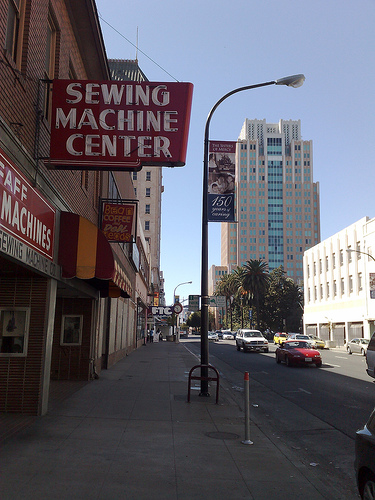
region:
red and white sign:
[51, 75, 181, 180]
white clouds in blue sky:
[132, 14, 160, 29]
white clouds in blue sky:
[173, 214, 201, 255]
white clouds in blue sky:
[328, 124, 357, 158]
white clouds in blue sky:
[324, 49, 358, 88]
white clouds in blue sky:
[178, 26, 216, 71]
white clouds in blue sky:
[243, 29, 291, 57]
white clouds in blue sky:
[144, 6, 209, 43]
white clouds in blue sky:
[227, 25, 271, 67]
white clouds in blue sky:
[176, 18, 234, 52]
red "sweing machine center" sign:
[50, 76, 191, 163]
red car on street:
[270, 338, 321, 366]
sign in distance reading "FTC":
[151, 305, 172, 317]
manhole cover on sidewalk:
[203, 424, 243, 444]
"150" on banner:
[210, 193, 233, 211]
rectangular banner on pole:
[206, 140, 238, 221]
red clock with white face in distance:
[173, 300, 183, 313]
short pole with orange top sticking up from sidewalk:
[240, 369, 256, 446]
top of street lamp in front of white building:
[340, 245, 374, 266]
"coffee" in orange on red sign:
[99, 211, 134, 222]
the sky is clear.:
[93, 2, 372, 295]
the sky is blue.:
[92, 2, 373, 283]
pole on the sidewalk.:
[240, 366, 253, 446]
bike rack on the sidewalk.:
[180, 353, 225, 401]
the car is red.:
[270, 331, 323, 369]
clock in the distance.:
[171, 299, 183, 313]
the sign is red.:
[45, 68, 196, 173]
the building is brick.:
[1, 0, 151, 301]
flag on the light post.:
[199, 130, 241, 231]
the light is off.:
[269, 67, 309, 94]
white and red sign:
[36, 64, 188, 169]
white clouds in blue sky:
[308, 119, 350, 171]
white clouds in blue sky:
[321, 148, 357, 224]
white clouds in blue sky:
[116, 19, 224, 68]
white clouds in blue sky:
[162, 10, 218, 63]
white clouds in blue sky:
[282, 15, 350, 61]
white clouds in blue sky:
[313, 41, 349, 101]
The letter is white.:
[65, 128, 85, 158]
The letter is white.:
[79, 131, 103, 156]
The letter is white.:
[99, 131, 118, 161]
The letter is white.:
[115, 130, 136, 158]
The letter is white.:
[135, 133, 154, 160]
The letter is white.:
[150, 133, 173, 159]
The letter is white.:
[52, 103, 78, 132]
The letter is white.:
[159, 107, 182, 134]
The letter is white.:
[60, 78, 85, 106]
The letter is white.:
[149, 81, 173, 111]